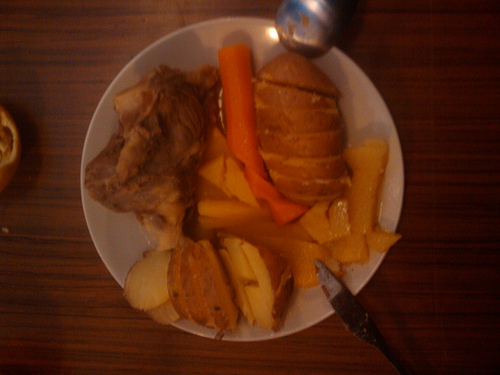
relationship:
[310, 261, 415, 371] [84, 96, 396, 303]
knife on plate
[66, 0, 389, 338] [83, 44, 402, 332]
plate full dinner meal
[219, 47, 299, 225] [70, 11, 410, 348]
carrot are on plate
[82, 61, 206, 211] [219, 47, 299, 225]
meat next to carrot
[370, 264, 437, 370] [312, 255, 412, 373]
shadow of knife